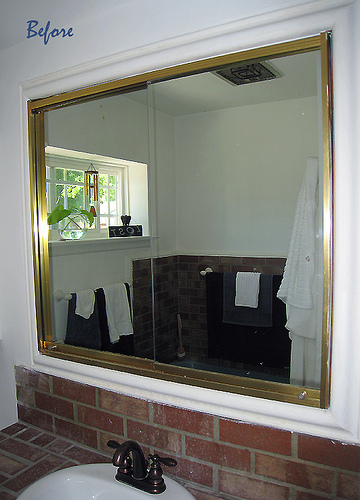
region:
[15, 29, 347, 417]
Big mirror on wall.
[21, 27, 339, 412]
Mirror has golden borders.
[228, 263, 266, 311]
White towel is reflected on mirror.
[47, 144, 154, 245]
Window reflected on mirror is white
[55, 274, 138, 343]
Rack is white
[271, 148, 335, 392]
Bath Cloth hangs from hanger in wall.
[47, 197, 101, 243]
Large leaves in vase.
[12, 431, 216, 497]
White sink on a brick counter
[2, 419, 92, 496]
Counter is made of brick.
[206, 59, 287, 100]
Bathroom extractor fan on ceiling.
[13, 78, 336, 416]
large bathroom mirror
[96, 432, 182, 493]
bathroom faucet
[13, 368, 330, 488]
brick counter top and back splash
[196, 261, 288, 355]
reflection of towels hanging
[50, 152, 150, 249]
reflection of window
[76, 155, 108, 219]
wind chimes hanging in window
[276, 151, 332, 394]
reflection of bathrobe hanging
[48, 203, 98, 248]
green leaves in bowl of water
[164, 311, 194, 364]
reflection of toilet brush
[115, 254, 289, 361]
stylized brick wall panel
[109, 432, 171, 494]
bronze fixtures on a sink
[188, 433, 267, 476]
red bricks in a wall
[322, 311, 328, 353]
gold frame of a mirror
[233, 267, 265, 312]
a white hand towel reflected in the mirror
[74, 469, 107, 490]
a white porcelain sink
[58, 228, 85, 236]
a glass bowl of water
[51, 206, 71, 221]
a bright green plant leaf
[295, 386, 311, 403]
a silver metal screw in the mirror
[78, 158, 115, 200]
windchimes hanging at a window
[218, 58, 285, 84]
a black vent in the celiling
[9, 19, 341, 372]
a brass trimmed mirror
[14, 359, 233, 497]
a wall made of brick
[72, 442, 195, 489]
a bathroom sink faucet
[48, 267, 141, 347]
two white towels hanging on a rod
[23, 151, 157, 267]
a window with a large ledge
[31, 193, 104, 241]
a plant in a glass bowl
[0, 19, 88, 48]
the word before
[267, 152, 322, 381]
a white house coat hanging on a hook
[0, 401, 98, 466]
several bricks with cement holding them in place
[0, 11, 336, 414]
reflection of a room in a mirro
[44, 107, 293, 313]
this is a glass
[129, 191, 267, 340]
the glass is transparent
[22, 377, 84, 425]
this is a wall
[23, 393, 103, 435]
the wall is made of bricks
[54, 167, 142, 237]
this is a window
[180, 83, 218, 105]
this is the roof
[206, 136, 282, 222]
this is a wall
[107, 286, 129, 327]
this is a towel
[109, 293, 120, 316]
the towel is white in color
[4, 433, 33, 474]
this is the floor